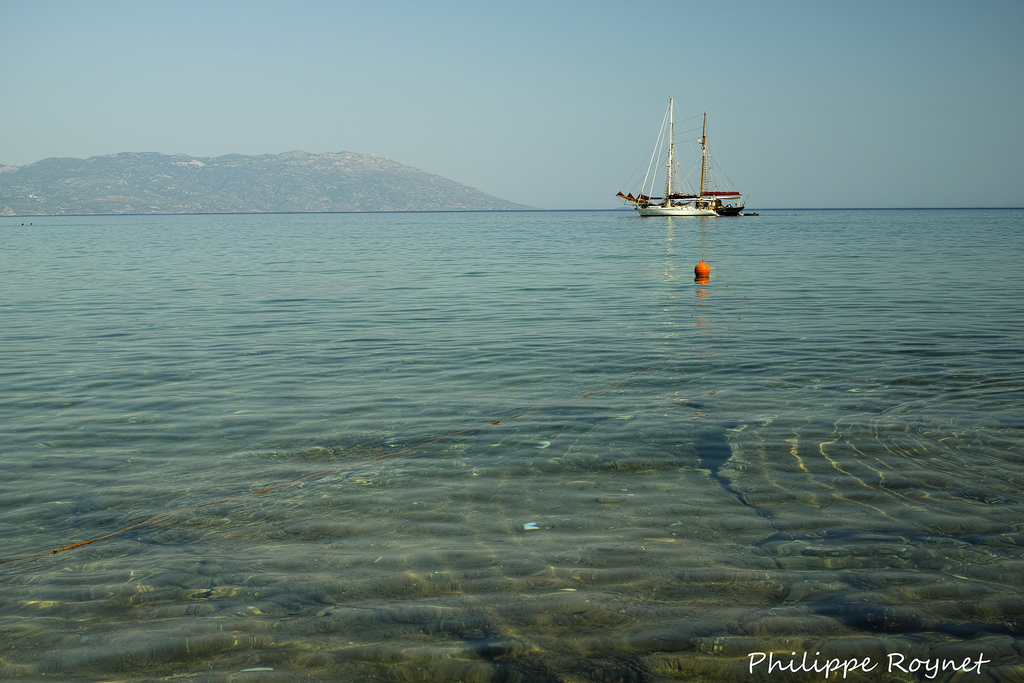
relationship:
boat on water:
[597, 114, 733, 229] [23, 348, 1004, 674]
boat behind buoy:
[597, 114, 733, 229] [679, 254, 709, 299]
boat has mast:
[597, 114, 733, 229] [648, 72, 677, 201]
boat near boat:
[616, 96, 759, 216] [597, 114, 733, 229]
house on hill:
[159, 146, 225, 172] [9, 151, 527, 189]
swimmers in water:
[785, 203, 821, 227] [23, 348, 1004, 674]